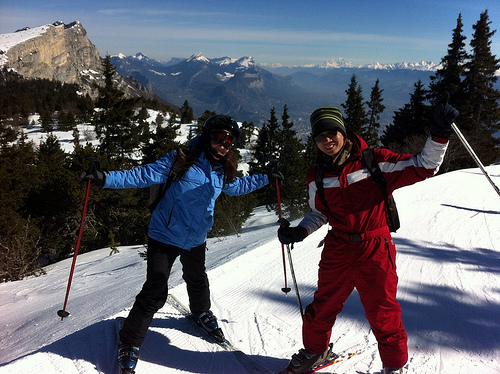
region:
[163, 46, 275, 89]
mountainside covered in snow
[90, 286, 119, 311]
ground covered in snow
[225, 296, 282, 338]
ski tracks in snow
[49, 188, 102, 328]
red metal ski pole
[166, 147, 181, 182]
black backpack strap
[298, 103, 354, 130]
black and green ski cap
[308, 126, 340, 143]
black sun glasse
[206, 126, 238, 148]
red and black safety glasses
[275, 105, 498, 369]
man in red ski suit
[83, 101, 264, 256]
person in blue jacket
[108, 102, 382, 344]
people are dressed for skiing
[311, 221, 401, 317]
person wearing red pants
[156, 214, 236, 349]
lady wearing black pants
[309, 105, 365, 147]
person wearing striped cap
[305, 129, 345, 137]
person wearing dark sunglasses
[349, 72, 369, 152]
pine tree in background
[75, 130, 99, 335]
woman has red ski pole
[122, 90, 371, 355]
people standing in snow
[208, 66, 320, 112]
mountain range in distance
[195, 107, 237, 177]
woman wearing black helmet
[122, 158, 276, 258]
the shirt is blue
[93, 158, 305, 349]
the shirt is blue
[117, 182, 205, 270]
the shirt is blue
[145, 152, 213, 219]
the shirt is blue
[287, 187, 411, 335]
the shirt is red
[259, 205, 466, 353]
the shirt is red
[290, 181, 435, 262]
the shirt is red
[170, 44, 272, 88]
snow covered mountain tops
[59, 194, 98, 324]
metal red ski pole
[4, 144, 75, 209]
trees with green leaves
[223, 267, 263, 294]
ground covered in snow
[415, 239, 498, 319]
ski tracks in snow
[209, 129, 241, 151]
black and red safety googles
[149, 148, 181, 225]
black backpack straps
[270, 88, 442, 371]
man in red and white ski suit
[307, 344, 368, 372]
red and yellow ski